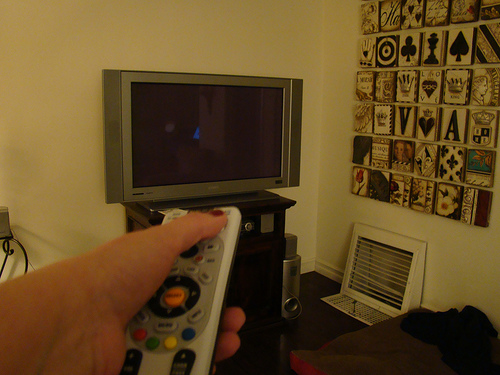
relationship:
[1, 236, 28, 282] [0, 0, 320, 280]
wires running down wall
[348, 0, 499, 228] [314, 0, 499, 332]
artwork on wall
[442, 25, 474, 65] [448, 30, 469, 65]
tile with spade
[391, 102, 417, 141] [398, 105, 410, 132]
tile with v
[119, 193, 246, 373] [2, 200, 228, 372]
remote in hand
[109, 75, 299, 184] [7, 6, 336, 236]
tv against wall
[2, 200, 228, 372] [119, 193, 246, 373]
hand holding remote